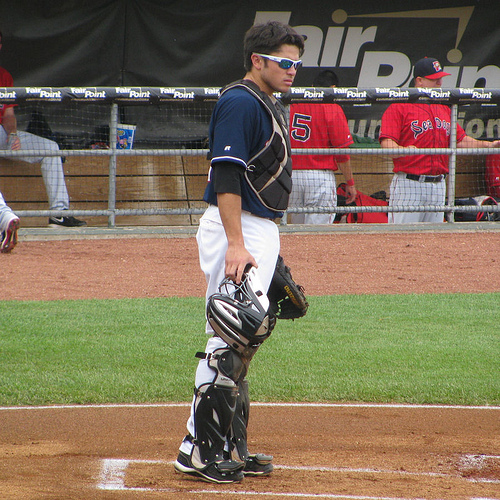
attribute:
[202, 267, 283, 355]
helmet — silver, black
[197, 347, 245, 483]
knee and shin pads — black, silver, protective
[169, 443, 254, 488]
sneakers — black, white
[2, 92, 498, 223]
chainlink fence — gray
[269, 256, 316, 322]
baseball glove — black, yellow